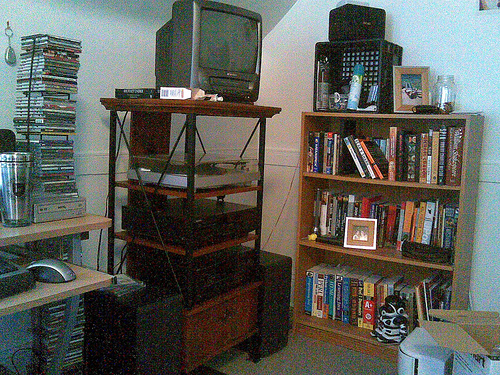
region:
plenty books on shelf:
[284, 127, 435, 317]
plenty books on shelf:
[230, 60, 420, 280]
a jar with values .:
[430, 71, 460, 112]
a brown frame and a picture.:
[388, 62, 433, 114]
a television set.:
[161, 4, 266, 102]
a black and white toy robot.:
[363, 291, 423, 341]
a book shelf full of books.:
[293, 115, 474, 313]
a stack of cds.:
[31, 35, 84, 195]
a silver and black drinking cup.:
[0, 144, 35, 236]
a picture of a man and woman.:
[338, 218, 379, 248]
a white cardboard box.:
[411, 296, 499, 373]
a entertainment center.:
[3, 2, 298, 374]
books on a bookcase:
[289, 117, 499, 347]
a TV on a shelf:
[100, 5, 328, 369]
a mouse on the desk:
[25, 247, 78, 282]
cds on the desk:
[0, 37, 90, 204]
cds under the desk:
[44, 233, 99, 371]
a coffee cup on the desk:
[0, 141, 53, 228]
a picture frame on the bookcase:
[328, 204, 393, 255]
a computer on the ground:
[239, 219, 332, 368]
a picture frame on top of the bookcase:
[385, 57, 446, 138]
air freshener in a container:
[340, 57, 370, 127]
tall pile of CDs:
[21, 35, 78, 196]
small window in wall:
[463, 0, 489, 22]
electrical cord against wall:
[270, 172, 297, 251]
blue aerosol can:
[343, 60, 370, 115]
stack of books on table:
[9, 24, 92, 219]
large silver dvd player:
[19, 189, 120, 233]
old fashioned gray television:
[178, 9, 284, 106]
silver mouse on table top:
[27, 253, 109, 287]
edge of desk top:
[72, 269, 115, 304]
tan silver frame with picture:
[382, 56, 441, 123]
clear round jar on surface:
[431, 64, 461, 124]